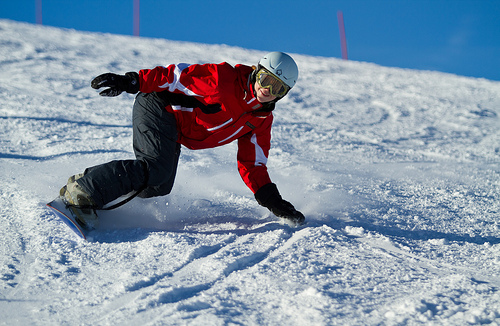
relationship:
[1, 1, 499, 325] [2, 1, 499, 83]
photo has sky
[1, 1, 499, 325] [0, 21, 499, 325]
photo has snow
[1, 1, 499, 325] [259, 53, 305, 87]
photo has helmet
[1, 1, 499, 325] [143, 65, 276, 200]
photo has jacket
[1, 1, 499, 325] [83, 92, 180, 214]
photo has trouser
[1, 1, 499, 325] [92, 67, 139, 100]
photo has glove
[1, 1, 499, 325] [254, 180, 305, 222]
photo has glove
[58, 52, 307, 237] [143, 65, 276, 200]
woman has jacket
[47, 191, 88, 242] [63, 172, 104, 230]
snowboard on feet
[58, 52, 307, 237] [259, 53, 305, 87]
woman has helmet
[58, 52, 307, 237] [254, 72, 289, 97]
woman has goggles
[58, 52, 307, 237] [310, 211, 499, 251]
woman has shadow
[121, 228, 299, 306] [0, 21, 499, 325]
tracks in snow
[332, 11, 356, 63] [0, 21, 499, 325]
pole on snow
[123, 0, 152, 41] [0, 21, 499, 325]
pole on snow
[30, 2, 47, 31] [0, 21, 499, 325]
pole on snow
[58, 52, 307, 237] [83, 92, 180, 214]
woman has trouser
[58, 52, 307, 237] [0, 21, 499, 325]
woman touching snow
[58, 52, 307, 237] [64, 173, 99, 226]
woman has shoes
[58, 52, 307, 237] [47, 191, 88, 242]
woman on snowboard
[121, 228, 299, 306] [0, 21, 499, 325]
tracks on snow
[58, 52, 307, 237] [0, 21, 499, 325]
woman on snow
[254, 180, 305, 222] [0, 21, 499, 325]
glove touching snow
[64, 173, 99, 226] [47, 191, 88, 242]
shoes on snowboard